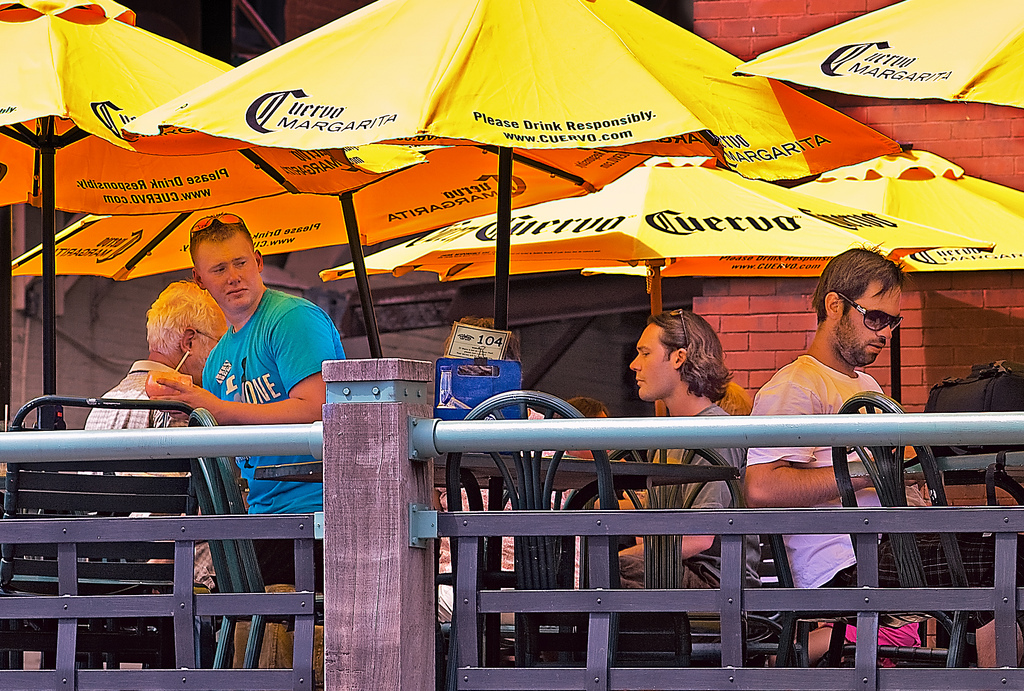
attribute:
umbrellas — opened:
[20, 12, 1014, 428]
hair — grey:
[642, 305, 740, 385]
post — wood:
[323, 344, 449, 625]